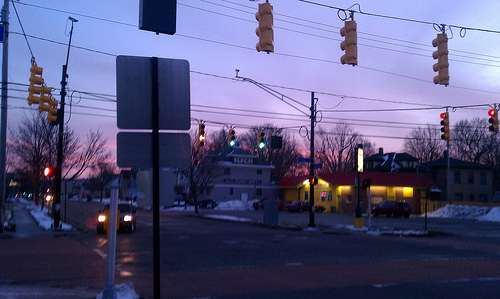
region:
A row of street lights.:
[193, 116, 274, 158]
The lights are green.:
[224, 125, 269, 157]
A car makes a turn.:
[80, 197, 142, 239]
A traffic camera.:
[231, 66, 244, 81]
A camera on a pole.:
[57, 12, 82, 117]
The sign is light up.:
[351, 137, 368, 219]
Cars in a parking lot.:
[252, 192, 419, 222]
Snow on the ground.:
[341, 220, 441, 240]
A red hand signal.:
[35, 164, 57, 180]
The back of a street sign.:
[112, 49, 197, 297]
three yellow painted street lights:
[252, 2, 474, 97]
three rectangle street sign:
[110, 50, 220, 292]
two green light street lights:
[223, 124, 280, 159]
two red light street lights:
[439, 105, 496, 150]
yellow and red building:
[279, 157, 464, 249]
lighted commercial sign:
[350, 142, 375, 236]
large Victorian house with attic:
[192, 145, 287, 210]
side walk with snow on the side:
[11, 192, 63, 236]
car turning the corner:
[22, 153, 179, 270]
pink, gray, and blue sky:
[248, 74, 473, 171]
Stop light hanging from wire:
[315, 10, 409, 72]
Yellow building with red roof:
[296, 170, 461, 231]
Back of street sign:
[115, 56, 206, 200]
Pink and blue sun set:
[98, 90, 382, 210]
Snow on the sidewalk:
[10, 176, 69, 243]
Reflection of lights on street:
[87, 229, 169, 295]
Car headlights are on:
[78, 197, 133, 242]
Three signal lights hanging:
[16, 60, 91, 155]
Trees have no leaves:
[243, 118, 484, 185]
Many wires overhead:
[213, 68, 495, 217]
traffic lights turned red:
[407, 95, 494, 155]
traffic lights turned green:
[213, 122, 279, 173]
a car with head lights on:
[67, 185, 138, 232]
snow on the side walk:
[15, 193, 75, 244]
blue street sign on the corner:
[287, 142, 336, 232]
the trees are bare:
[6, 115, 91, 194]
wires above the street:
[195, 47, 409, 158]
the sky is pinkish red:
[217, 105, 372, 172]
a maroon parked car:
[338, 189, 414, 221]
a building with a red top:
[270, 137, 420, 215]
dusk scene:
[27, 140, 128, 240]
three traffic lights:
[194, 110, 294, 182]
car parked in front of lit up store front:
[332, 159, 424, 245]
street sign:
[93, 36, 221, 231]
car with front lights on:
[79, 184, 156, 256]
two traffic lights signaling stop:
[390, 92, 498, 162]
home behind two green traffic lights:
[206, 130, 281, 222]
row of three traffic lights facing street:
[253, 6, 463, 105]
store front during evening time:
[288, 165, 434, 232]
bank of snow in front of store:
[405, 180, 498, 250]